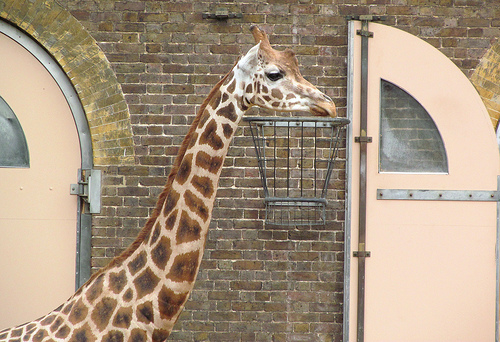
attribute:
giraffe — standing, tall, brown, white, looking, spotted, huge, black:
[182, 37, 340, 179]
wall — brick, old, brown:
[104, 16, 184, 102]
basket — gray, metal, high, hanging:
[248, 117, 342, 222]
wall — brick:
[0, 0, 500, 340]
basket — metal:
[243, 112, 349, 226]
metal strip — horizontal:
[376, 185, 498, 204]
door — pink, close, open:
[347, 17, 498, 340]